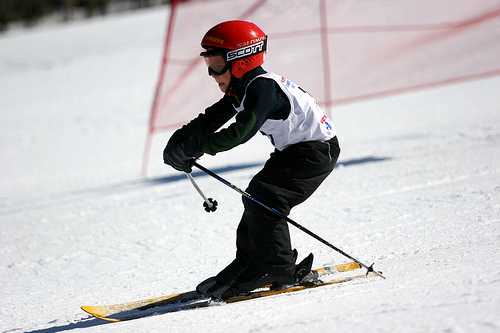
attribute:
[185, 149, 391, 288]
ski pole — black, blue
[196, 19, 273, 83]
helmet — child sized, red, plastic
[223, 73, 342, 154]
jersey — white, child sized, black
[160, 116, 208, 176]
gloves — small, black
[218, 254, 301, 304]
boot — black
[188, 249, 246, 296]
boot — black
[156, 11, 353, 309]
boy — skiing, crouched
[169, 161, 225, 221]
ski pole — silver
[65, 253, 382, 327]
skis — yellow, long, skinny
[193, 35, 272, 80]
goggles — black, white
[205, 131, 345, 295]
pants — black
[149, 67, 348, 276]
suit — black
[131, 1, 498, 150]
snow fence — orangish